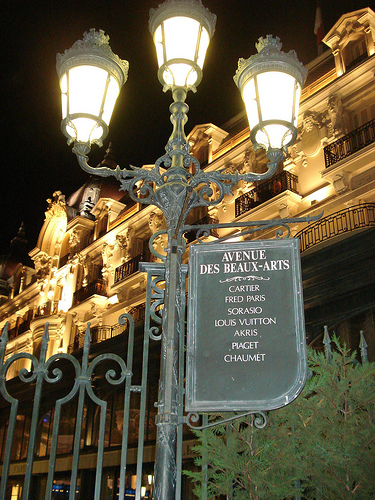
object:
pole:
[135, 170, 200, 499]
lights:
[231, 31, 309, 153]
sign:
[182, 233, 307, 426]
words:
[226, 282, 262, 295]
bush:
[220, 343, 375, 498]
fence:
[3, 309, 171, 498]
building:
[0, 11, 374, 384]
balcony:
[69, 246, 109, 311]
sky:
[0, 1, 145, 49]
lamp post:
[71, 108, 291, 500]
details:
[32, 222, 146, 313]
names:
[224, 292, 268, 307]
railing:
[232, 167, 300, 220]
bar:
[183, 211, 326, 244]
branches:
[316, 343, 375, 499]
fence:
[310, 321, 373, 375]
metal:
[4, 345, 140, 412]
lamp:
[232, 32, 309, 156]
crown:
[252, 34, 284, 52]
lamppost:
[54, 0, 313, 235]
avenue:
[219, 248, 267, 263]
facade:
[27, 176, 125, 312]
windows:
[84, 255, 106, 300]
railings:
[320, 113, 374, 175]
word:
[228, 282, 261, 294]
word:
[225, 308, 230, 317]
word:
[244, 292, 266, 305]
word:
[226, 305, 262, 317]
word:
[211, 317, 240, 329]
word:
[269, 315, 278, 327]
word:
[230, 328, 258, 340]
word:
[230, 339, 261, 350]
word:
[222, 352, 265, 366]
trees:
[226, 391, 289, 499]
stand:
[149, 232, 182, 499]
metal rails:
[118, 309, 135, 499]